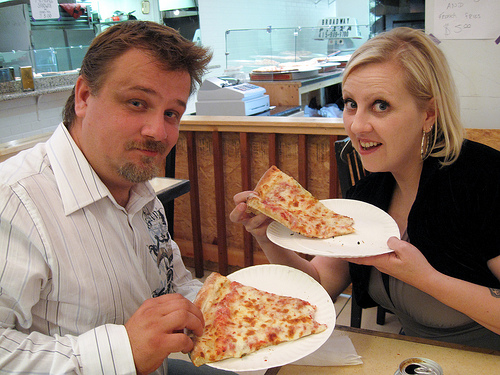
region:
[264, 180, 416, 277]
A white paper plate.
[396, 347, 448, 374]
The top of a soda can.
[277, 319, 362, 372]
A white napkin.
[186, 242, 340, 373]
A slice of pizza on a white plate.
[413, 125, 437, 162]
A silver hoop earring.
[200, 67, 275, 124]
A cash register.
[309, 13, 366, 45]
A pizza delivery car sign.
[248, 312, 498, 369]
A light colored tabletop.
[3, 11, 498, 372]
Two people about to eat pizza.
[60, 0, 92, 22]
A red pizza bag.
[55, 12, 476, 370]
Couple enjoying their delicious pizza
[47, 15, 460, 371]
Couple having lunch in a restaurant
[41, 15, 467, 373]
Couple eating in a pizza parlor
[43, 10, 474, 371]
Couple enjoying their pizza dinner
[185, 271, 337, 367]
A slice of pizza on a paper plate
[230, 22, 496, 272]
Woman enjoying her tasty pizza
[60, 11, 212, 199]
Man with dark colored hair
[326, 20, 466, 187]
Woman with blond colored hair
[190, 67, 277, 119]
Cash register in a restaurant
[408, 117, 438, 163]
Ear ring hanging from somebody's ear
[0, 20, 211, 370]
man sitting at table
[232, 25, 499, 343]
woman sitting at table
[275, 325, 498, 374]
light colored table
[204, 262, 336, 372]
round white paper plate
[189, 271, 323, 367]
triangle pizza on plate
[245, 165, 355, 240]
pizza held by woman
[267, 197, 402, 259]
white paper plate in womans hand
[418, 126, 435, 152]
earring on woman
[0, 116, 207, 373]
striped white shirt on man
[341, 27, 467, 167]
short blonde hair on woman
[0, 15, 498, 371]
Two people are sitting next to each other.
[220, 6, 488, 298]
The woman is holding a paper plate with pizza.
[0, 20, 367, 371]
The man is holding a paper plate with pizza.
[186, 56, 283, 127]
A cash register in the background.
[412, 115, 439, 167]
A hoop earring on the woman's ear.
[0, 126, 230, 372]
The man is wearing a button up white shirt with stripes.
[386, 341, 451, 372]
The top of a soda can.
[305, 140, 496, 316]
The woman is wearing black.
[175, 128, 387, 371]
Cheese pizza is on the paper plates.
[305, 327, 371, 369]
A napkin is on the table.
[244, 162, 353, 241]
a piece of pizza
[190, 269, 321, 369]
a piece of pizza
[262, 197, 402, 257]
a white paper plate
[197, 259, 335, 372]
a white paper plate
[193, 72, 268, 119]
a white cash register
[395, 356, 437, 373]
an open soda can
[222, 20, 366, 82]
a glass display case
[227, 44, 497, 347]
a woman sitting at table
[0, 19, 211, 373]
a man sitting at table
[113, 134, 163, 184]
a man's goatee